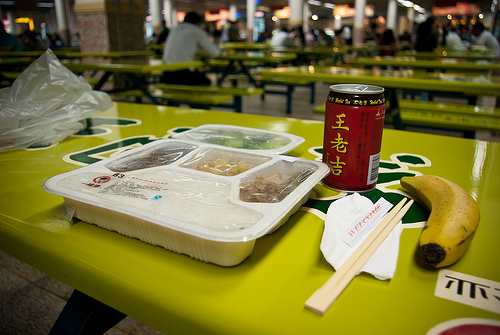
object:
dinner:
[56, 125, 321, 233]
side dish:
[188, 125, 289, 150]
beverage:
[320, 80, 388, 194]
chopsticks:
[301, 195, 418, 318]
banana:
[396, 170, 484, 270]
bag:
[0, 45, 115, 148]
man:
[159, 9, 226, 89]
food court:
[2, 1, 499, 334]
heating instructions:
[92, 172, 164, 201]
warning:
[92, 170, 112, 188]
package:
[41, 122, 415, 321]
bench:
[387, 103, 500, 133]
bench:
[112, 86, 234, 105]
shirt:
[159, 22, 227, 67]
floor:
[2, 57, 499, 334]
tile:
[1, 263, 135, 334]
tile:
[1, 248, 49, 307]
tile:
[31, 274, 81, 301]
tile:
[98, 324, 128, 334]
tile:
[113, 314, 167, 334]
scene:
[1, 1, 498, 334]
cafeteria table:
[2, 100, 500, 333]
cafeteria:
[1, 1, 499, 334]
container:
[38, 120, 337, 269]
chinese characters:
[325, 154, 350, 176]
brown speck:
[445, 245, 454, 254]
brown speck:
[446, 199, 451, 204]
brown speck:
[435, 177, 440, 182]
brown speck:
[464, 210, 469, 216]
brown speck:
[457, 235, 464, 240]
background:
[3, 1, 499, 116]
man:
[468, 20, 499, 52]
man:
[441, 25, 470, 53]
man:
[268, 25, 295, 48]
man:
[0, 20, 29, 57]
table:
[241, 63, 494, 107]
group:
[0, 1, 499, 54]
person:
[370, 12, 398, 46]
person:
[412, 13, 446, 54]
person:
[331, 26, 347, 50]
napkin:
[317, 190, 406, 284]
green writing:
[25, 113, 436, 232]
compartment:
[234, 156, 329, 206]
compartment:
[43, 164, 272, 273]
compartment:
[100, 138, 200, 175]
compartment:
[169, 143, 279, 180]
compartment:
[169, 124, 307, 155]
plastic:
[40, 122, 331, 244]